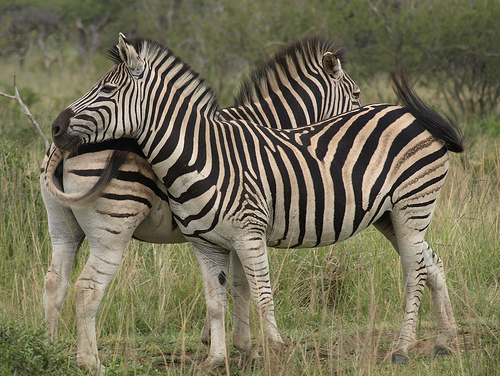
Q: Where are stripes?
A: On the zebra.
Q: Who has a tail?
A: The zebra.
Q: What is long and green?
A: Grass.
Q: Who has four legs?
A: One zebra.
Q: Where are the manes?
A: On zebra's necks.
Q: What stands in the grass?
A: Two zebras.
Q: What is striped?
A: The zebra's fur.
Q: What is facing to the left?
A: A zebra.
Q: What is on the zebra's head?
A: A black and white mane.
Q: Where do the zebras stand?
A: In a field of high grass.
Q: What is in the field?
A: Two zebras standing next to each other.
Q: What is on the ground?
A: Tall grass.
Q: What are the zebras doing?
A: Standing in a field.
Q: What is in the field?
A: Two zebras standing together.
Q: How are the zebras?
A: Standing.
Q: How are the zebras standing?
A: Together.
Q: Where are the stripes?
A: Zebras.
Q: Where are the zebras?
A: In field.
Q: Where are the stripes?
A: On zebras.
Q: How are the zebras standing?
A: Different directions.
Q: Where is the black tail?
A: On zebra.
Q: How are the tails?
A: Swishing.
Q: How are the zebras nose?
A: Black.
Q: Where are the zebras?
A: In a field.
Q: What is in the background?
A: Trees.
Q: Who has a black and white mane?
A: The zebra.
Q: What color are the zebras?
A: White and black.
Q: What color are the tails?
A: Black.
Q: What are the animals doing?
A: Standing.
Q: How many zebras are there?
A: 2.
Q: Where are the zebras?
A: Field.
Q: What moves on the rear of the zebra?
A: Tail.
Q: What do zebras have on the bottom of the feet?
A: Hooves.